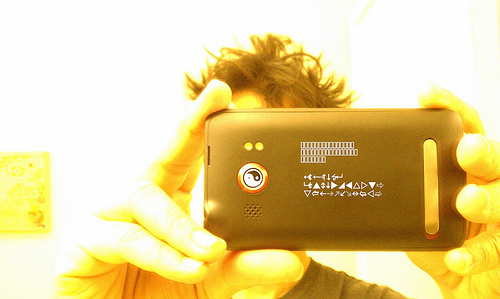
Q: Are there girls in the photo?
A: No, there are no girls.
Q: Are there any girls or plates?
A: No, there are no girls or plates.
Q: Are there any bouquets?
A: No, there are no bouquets.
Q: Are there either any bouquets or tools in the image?
A: No, there are no bouquets or tools.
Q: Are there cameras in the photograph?
A: Yes, there is a camera.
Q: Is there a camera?
A: Yes, there is a camera.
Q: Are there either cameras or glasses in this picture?
A: Yes, there is a camera.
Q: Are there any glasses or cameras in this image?
A: Yes, there is a camera.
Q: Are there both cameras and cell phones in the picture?
A: Yes, there are both a camera and a cell phone.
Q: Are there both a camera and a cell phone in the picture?
A: Yes, there are both a camera and a cell phone.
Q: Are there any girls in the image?
A: No, there are no girls.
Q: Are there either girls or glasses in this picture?
A: No, there are no girls or glasses.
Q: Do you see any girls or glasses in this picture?
A: No, there are no girls or glasses.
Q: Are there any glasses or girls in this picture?
A: No, there are no girls or glasses.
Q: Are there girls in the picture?
A: No, there are no girls.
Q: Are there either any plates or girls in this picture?
A: No, there are no girls or plates.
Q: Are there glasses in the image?
A: No, there are no glasses.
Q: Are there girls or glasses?
A: No, there are no glasses or girls.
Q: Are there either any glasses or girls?
A: No, there are no glasses or girls.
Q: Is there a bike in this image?
A: No, there are no bikes.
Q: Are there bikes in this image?
A: No, there are no bikes.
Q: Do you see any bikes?
A: No, there are no bikes.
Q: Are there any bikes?
A: No, there are no bikes.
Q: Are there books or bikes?
A: No, there are no bikes or books.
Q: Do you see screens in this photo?
A: No, there are no screens.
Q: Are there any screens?
A: No, there are no screens.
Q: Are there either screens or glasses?
A: No, there are no screens or glasses.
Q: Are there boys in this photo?
A: No, there are no boys.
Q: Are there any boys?
A: No, there are no boys.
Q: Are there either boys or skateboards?
A: No, there are no boys or skateboards.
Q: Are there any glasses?
A: No, there are no glasses.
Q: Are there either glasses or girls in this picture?
A: No, there are no glasses or girls.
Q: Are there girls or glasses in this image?
A: No, there are no glasses or girls.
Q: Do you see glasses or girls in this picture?
A: No, there are no glasses or girls.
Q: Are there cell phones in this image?
A: Yes, there is a cell phone.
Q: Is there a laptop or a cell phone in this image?
A: Yes, there is a cell phone.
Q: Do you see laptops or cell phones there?
A: Yes, there is a cell phone.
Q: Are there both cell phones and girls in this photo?
A: No, there is a cell phone but no girls.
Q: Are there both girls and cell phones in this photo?
A: No, there is a cell phone but no girls.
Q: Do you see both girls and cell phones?
A: No, there is a cell phone but no girls.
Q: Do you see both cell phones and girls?
A: No, there is a cell phone but no girls.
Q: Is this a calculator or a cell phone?
A: This is a cell phone.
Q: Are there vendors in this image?
A: No, there are no vendors.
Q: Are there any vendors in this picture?
A: No, there are no vendors.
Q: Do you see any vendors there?
A: No, there are no vendors.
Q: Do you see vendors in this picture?
A: No, there are no vendors.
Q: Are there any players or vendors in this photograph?
A: No, there are no vendors or players.